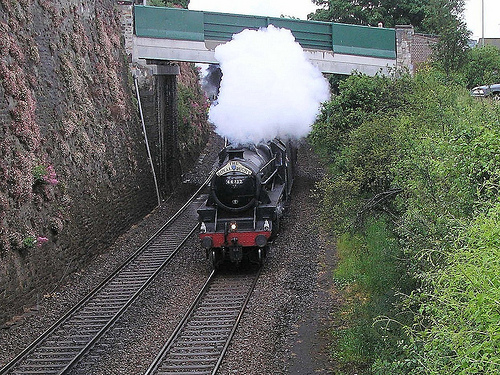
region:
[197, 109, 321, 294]
locomotive on the track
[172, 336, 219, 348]
cross tie on the track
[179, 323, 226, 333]
cross tie on the track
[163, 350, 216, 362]
cross tie on the track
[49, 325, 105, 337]
cross tie on the track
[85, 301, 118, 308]
cross tie on the track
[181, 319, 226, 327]
cross tie on the track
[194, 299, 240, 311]
cross tie on the track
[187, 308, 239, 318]
cross tie on the track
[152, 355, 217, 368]
cross tie on the track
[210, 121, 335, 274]
this is a train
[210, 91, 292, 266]
the train is black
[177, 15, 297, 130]
this is opaque steam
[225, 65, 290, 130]
the steam is white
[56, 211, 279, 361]
this is a train track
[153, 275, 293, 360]
the track is dark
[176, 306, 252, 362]
the track is metal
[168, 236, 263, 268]
these are wheels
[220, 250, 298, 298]
the wheels are black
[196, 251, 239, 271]
the wheels are metal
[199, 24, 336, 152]
steam coming up from train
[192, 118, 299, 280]
black train with red bumper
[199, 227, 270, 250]
red bumper on train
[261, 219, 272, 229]
Letter A front right side of train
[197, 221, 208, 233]
Letter A front left side of train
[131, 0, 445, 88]
overpass above train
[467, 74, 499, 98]
car getting ready to go over the overpass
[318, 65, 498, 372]
green shrubbery to the right side of the train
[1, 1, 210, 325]
large rock wall to the left side of train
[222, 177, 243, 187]
series of numbers on the train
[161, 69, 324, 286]
a steam engine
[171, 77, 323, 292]
a black steam engine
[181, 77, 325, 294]
a black engine train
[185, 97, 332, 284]
a black steam engine train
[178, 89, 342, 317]
the train is on the tracks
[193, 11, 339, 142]
steam from the train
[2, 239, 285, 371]
there is gravel in between the tracks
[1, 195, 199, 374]
empty train tracks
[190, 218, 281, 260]
the bumper is red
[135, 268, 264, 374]
iron train rails and tracks